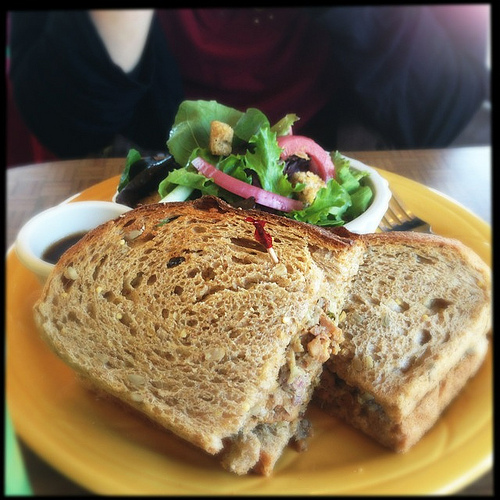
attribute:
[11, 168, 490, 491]
plate — yellow, a color, an off hue, clean, round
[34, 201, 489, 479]
sandwich — together, cut in half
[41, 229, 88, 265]
sauce — a dressing, brown, au jus, for dipping, dark, inside cup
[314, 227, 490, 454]
bread — grain filled, for half, oat flavored, brown, honey flavored, toasted, sliced, wheat type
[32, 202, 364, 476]
bread — toasted, sliced, grain filled, for half, oat flavored, brown, honey flavored, wheat type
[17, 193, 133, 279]
dish — small, white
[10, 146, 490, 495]
table — wooden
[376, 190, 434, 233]
fork — metal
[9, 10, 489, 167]
person — woman, sitting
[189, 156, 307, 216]
onion — red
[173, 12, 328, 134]
scarf — red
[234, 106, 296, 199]
lettuce — green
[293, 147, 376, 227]
lettuce — green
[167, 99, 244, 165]
lettuce — green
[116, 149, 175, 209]
lettuce — green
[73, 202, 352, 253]
crust — brown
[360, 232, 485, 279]
crust — brown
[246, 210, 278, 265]
toothpick — for holding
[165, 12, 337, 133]
shirt — red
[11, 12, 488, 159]
sweater — black